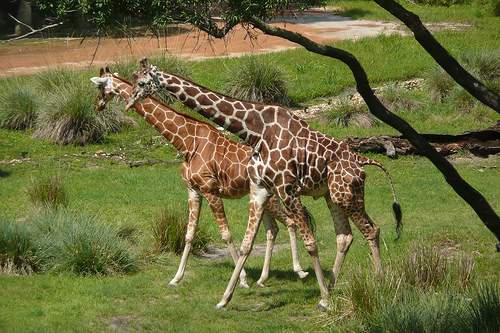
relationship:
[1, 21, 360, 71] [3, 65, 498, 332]
pond beside grass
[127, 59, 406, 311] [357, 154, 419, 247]
giraffe has tail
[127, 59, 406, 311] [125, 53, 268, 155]
giraffe has neck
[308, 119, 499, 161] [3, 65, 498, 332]
trunk on grass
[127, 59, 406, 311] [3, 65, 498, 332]
giraffe on grass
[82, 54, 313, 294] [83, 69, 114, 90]
giraffe has ear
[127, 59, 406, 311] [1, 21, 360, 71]
giraffe near pond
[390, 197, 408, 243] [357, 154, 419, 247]
hair on tail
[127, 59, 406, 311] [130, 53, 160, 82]
giraffe has nubs